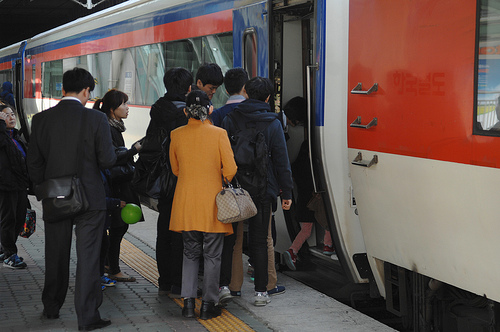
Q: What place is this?
A: It is a station.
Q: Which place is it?
A: It is a station.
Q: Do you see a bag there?
A: Yes, there is a bag.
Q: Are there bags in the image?
A: Yes, there is a bag.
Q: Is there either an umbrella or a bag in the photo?
A: Yes, there is a bag.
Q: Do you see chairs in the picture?
A: No, there are no chairs.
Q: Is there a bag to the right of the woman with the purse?
A: Yes, there is a bag to the right of the woman.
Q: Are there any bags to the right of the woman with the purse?
A: Yes, there is a bag to the right of the woman.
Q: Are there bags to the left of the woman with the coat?
A: No, the bag is to the right of the woman.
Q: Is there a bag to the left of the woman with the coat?
A: No, the bag is to the right of the woman.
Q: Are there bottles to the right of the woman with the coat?
A: No, there is a bag to the right of the woman.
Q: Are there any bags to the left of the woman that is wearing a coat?
A: Yes, there is a bag to the left of the woman.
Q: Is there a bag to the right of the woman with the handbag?
A: No, the bag is to the left of the woman.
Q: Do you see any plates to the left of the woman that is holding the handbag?
A: No, there is a bag to the left of the woman.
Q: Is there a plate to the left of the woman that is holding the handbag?
A: No, there is a bag to the left of the woman.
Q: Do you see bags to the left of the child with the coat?
A: Yes, there is a bag to the left of the child.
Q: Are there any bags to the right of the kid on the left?
A: No, the bag is to the left of the child.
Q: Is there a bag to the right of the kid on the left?
A: No, the bag is to the left of the child.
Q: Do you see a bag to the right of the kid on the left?
A: No, the bag is to the left of the child.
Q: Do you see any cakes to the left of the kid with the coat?
A: No, there is a bag to the left of the child.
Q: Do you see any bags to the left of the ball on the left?
A: Yes, there is a bag to the left of the ball.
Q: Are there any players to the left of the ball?
A: No, there is a bag to the left of the ball.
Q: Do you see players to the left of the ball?
A: No, there is a bag to the left of the ball.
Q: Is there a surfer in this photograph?
A: No, there are no surfers.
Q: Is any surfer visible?
A: No, there are no surfers.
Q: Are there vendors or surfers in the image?
A: No, there are no surfers or vendors.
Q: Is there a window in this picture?
A: Yes, there is a window.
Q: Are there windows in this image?
A: Yes, there is a window.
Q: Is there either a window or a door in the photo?
A: Yes, there is a window.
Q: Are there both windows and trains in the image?
A: Yes, there are both a window and a train.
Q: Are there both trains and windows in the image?
A: Yes, there are both a window and a train.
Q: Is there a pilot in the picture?
A: No, there are no pilots.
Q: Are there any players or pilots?
A: No, there are no pilots or players.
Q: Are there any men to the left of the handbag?
A: Yes, there is a man to the left of the handbag.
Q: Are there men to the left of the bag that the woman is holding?
A: Yes, there is a man to the left of the handbag.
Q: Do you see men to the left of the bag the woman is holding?
A: Yes, there is a man to the left of the handbag.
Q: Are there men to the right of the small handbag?
A: No, the man is to the left of the handbag.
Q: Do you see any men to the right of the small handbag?
A: No, the man is to the left of the handbag.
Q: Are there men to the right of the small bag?
A: No, the man is to the left of the handbag.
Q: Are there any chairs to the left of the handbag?
A: No, there is a man to the left of the handbag.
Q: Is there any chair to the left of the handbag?
A: No, there is a man to the left of the handbag.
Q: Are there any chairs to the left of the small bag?
A: No, there is a man to the left of the handbag.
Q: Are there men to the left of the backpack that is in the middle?
A: Yes, there is a man to the left of the backpack.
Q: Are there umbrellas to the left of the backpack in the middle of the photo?
A: No, there is a man to the left of the backpack.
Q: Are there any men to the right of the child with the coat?
A: Yes, there is a man to the right of the kid.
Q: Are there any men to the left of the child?
A: No, the man is to the right of the child.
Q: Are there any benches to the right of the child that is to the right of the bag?
A: No, there is a man to the right of the kid.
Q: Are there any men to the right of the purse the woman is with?
A: Yes, there is a man to the right of the purse.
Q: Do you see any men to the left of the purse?
A: No, the man is to the right of the purse.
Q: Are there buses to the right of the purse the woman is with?
A: No, there is a man to the right of the purse.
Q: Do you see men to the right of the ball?
A: Yes, there is a man to the right of the ball.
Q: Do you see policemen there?
A: No, there are no policemen.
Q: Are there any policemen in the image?
A: No, there are no policemen.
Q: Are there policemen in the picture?
A: No, there are no policemen.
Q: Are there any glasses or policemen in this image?
A: No, there are no policemen or glasses.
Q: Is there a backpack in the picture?
A: Yes, there is a backpack.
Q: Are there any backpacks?
A: Yes, there is a backpack.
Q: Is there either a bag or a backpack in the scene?
A: Yes, there is a backpack.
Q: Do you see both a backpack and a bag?
A: Yes, there are both a backpack and a bag.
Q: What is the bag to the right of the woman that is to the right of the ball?
A: The bag is a backpack.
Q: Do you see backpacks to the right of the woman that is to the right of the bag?
A: Yes, there is a backpack to the right of the woman.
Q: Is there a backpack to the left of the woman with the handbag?
A: No, the backpack is to the right of the woman.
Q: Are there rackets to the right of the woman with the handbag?
A: No, there is a backpack to the right of the woman.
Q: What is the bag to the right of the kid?
A: The bag is a backpack.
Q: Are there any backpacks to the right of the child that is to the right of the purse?
A: Yes, there is a backpack to the right of the kid.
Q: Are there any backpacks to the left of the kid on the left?
A: No, the backpack is to the right of the child.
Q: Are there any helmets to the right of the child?
A: No, there is a backpack to the right of the child.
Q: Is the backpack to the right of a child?
A: Yes, the backpack is to the right of a child.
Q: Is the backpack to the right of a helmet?
A: No, the backpack is to the right of a child.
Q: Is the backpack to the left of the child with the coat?
A: No, the backpack is to the right of the child.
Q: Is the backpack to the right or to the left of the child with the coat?
A: The backpack is to the right of the kid.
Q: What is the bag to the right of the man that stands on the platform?
A: The bag is a backpack.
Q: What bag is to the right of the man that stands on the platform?
A: The bag is a backpack.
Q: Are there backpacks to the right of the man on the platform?
A: Yes, there is a backpack to the right of the man.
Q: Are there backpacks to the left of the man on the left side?
A: No, the backpack is to the right of the man.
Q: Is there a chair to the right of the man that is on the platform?
A: No, there is a backpack to the right of the man.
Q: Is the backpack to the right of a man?
A: Yes, the backpack is to the right of a man.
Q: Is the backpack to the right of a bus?
A: No, the backpack is to the right of a man.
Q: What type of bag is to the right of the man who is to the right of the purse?
A: The bag is a backpack.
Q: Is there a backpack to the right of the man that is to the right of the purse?
A: Yes, there is a backpack to the right of the man.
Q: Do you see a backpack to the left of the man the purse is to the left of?
A: No, the backpack is to the right of the man.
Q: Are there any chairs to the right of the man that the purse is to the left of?
A: No, there is a backpack to the right of the man.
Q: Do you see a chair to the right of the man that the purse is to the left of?
A: No, there is a backpack to the right of the man.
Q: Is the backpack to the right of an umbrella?
A: No, the backpack is to the right of the man.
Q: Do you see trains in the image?
A: Yes, there is a train.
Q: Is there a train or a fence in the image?
A: Yes, there is a train.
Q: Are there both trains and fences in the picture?
A: No, there is a train but no fences.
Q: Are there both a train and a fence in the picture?
A: No, there is a train but no fences.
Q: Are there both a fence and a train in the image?
A: No, there is a train but no fences.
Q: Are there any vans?
A: No, there are no vans.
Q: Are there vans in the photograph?
A: No, there are no vans.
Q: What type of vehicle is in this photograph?
A: The vehicle is a train.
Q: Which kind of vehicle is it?
A: The vehicle is a train.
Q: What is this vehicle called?
A: That is a train.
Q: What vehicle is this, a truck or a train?
A: That is a train.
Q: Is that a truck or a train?
A: That is a train.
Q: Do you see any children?
A: Yes, there is a child.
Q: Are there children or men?
A: Yes, there is a child.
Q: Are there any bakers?
A: No, there are no bakers.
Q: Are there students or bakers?
A: No, there are no bakers or students.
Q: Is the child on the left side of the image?
A: Yes, the child is on the left of the image.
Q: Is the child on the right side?
A: No, the child is on the left of the image.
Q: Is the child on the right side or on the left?
A: The child is on the left of the image.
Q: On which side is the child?
A: The child is on the left of the image.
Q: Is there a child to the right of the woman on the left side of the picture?
A: Yes, there is a child to the right of the woman.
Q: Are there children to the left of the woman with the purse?
A: No, the child is to the right of the woman.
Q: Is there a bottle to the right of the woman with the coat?
A: No, there is a child to the right of the woman.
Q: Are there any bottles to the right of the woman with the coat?
A: No, there is a child to the right of the woman.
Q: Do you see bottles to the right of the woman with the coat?
A: No, there is a child to the right of the woman.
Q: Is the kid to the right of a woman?
A: Yes, the kid is to the right of a woman.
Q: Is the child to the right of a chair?
A: No, the child is to the right of a woman.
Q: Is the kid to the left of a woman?
A: No, the kid is to the right of a woman.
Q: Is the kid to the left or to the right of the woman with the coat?
A: The kid is to the right of the woman.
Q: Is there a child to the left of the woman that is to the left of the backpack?
A: Yes, there is a child to the left of the woman.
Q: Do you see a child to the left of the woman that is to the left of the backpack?
A: Yes, there is a child to the left of the woman.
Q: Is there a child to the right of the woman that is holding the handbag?
A: No, the child is to the left of the woman.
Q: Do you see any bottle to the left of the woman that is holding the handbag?
A: No, there is a child to the left of the woman.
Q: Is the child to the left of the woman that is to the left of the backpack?
A: Yes, the child is to the left of the woman.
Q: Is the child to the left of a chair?
A: No, the child is to the left of the woman.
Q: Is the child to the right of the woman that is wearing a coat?
A: No, the child is to the left of the woman.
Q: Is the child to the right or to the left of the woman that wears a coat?
A: The child is to the left of the woman.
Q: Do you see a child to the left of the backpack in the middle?
A: Yes, there is a child to the left of the backpack.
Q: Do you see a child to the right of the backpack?
A: No, the child is to the left of the backpack.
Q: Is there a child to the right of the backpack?
A: No, the child is to the left of the backpack.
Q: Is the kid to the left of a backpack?
A: Yes, the kid is to the left of a backpack.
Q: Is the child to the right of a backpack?
A: No, the child is to the left of a backpack.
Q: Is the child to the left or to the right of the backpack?
A: The child is to the left of the backpack.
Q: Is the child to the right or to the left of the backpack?
A: The child is to the left of the backpack.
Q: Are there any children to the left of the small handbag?
A: Yes, there is a child to the left of the handbag.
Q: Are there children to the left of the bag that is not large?
A: Yes, there is a child to the left of the handbag.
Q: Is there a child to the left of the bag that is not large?
A: Yes, there is a child to the left of the handbag.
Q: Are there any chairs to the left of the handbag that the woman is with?
A: No, there is a child to the left of the handbag.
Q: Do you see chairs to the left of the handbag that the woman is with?
A: No, there is a child to the left of the handbag.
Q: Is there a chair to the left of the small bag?
A: No, there is a child to the left of the handbag.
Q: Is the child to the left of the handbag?
A: Yes, the child is to the left of the handbag.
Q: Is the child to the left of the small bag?
A: Yes, the child is to the left of the handbag.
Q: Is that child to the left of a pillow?
A: No, the child is to the left of the handbag.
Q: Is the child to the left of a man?
A: Yes, the child is to the left of a man.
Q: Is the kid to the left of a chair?
A: No, the kid is to the left of a man.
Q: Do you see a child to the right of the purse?
A: Yes, there is a child to the right of the purse.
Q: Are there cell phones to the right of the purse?
A: No, there is a child to the right of the purse.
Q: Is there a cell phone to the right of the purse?
A: No, there is a child to the right of the purse.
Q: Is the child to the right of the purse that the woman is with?
A: Yes, the child is to the right of the purse.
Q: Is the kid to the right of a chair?
A: No, the kid is to the right of the purse.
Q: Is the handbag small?
A: Yes, the handbag is small.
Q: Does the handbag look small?
A: Yes, the handbag is small.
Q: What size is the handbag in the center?
A: The handbag is small.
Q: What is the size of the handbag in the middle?
A: The handbag is small.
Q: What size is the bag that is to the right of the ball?
A: The handbag is small.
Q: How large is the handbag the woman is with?
A: The handbag is small.